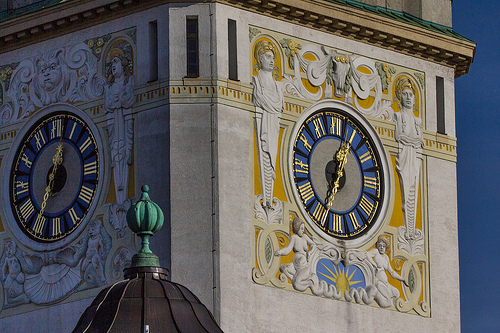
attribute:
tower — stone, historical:
[1, 0, 499, 332]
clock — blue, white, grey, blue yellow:
[291, 106, 385, 240]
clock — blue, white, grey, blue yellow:
[7, 108, 101, 242]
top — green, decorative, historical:
[122, 181, 165, 269]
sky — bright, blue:
[452, 0, 500, 332]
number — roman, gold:
[328, 115, 342, 137]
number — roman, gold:
[349, 127, 358, 146]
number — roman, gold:
[359, 148, 375, 163]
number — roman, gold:
[361, 173, 379, 193]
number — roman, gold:
[359, 195, 376, 215]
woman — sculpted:
[251, 40, 288, 212]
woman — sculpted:
[393, 77, 425, 239]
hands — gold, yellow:
[320, 141, 352, 223]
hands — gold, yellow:
[32, 140, 64, 231]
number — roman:
[350, 210, 361, 230]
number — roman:
[332, 212, 342, 235]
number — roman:
[312, 201, 332, 226]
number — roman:
[299, 179, 314, 204]